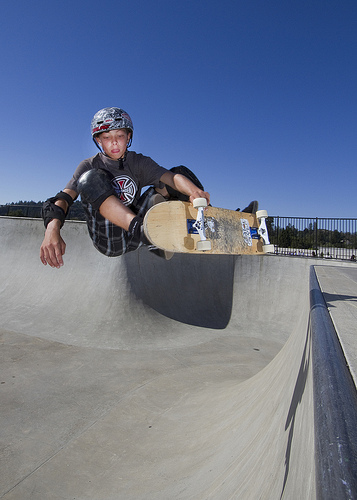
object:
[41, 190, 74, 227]
elbow pad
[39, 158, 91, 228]
arm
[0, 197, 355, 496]
park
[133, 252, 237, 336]
shadow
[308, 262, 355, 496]
bar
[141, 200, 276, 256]
skateboard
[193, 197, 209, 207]
wheel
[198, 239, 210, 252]
wheel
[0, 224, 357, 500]
skatepark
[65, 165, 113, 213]
pad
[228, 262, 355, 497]
ramp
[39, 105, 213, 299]
boy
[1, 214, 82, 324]
ramp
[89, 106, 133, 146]
helmet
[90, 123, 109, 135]
letters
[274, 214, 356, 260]
railing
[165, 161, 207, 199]
knee pad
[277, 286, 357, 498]
shadow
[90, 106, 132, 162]
head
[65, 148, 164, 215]
shirt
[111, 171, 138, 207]
emblem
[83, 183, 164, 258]
shorts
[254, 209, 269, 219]
wheel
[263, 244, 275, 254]
wheel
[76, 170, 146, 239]
leg